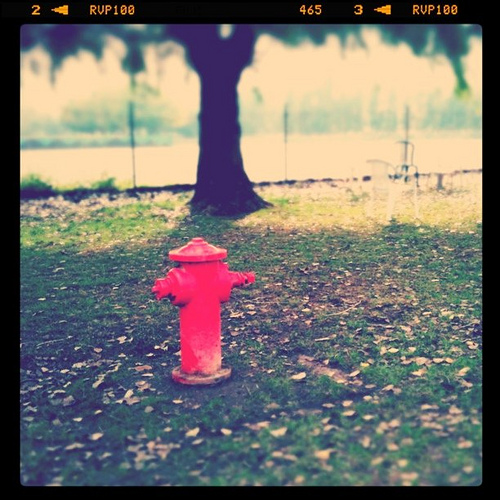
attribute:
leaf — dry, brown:
[291, 373, 306, 383]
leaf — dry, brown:
[271, 426, 286, 440]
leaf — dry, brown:
[218, 426, 235, 437]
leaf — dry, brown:
[185, 424, 200, 438]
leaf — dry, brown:
[88, 431, 99, 443]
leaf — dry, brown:
[315, 446, 332, 463]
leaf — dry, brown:
[412, 369, 426, 376]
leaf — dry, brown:
[457, 435, 472, 456]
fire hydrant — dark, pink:
[147, 230, 257, 387]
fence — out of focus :
[240, 57, 466, 237]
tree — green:
[22, 26, 466, 236]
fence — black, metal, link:
[19, 167, 481, 198]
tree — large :
[155, 30, 279, 227]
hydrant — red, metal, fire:
[150, 234, 257, 385]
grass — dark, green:
[20, 171, 482, 484]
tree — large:
[159, 24, 279, 213]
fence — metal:
[17, 90, 489, 172]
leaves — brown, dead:
[252, 207, 464, 420]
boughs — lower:
[238, 214, 412, 321]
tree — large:
[162, 34, 296, 176]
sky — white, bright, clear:
[19, 25, 483, 145]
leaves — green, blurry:
[327, 287, 432, 378]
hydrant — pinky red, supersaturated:
[155, 216, 302, 408]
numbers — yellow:
[295, 1, 326, 20]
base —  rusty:
[171, 362, 233, 387]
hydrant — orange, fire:
[89, 209, 280, 395]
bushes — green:
[19, 170, 144, 194]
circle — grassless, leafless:
[193, 365, 263, 436]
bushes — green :
[20, 74, 481, 149]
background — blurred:
[24, 30, 471, 216]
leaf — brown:
[452, 406, 465, 417]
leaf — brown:
[408, 368, 429, 381]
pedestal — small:
[167, 364, 246, 387]